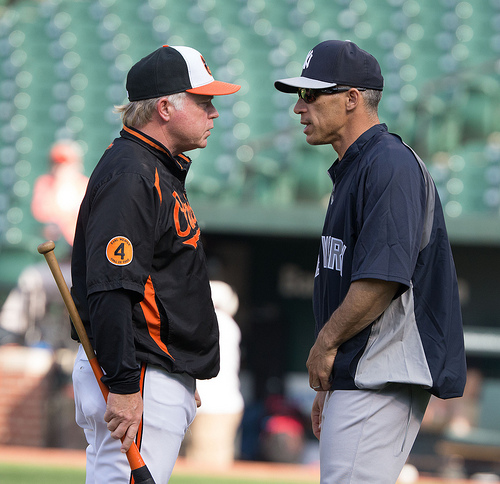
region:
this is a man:
[267, 18, 454, 481]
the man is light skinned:
[316, 104, 351, 126]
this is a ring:
[308, 379, 323, 392]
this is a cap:
[306, 43, 368, 76]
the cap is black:
[331, 41, 370, 84]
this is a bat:
[30, 237, 75, 324]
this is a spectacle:
[290, 90, 323, 103]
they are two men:
[61, 34, 363, 479]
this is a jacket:
[115, 186, 174, 294]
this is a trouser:
[343, 405, 390, 445]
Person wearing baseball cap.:
[283, 52, 386, 97]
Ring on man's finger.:
[309, 378, 326, 395]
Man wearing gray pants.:
[328, 414, 370, 452]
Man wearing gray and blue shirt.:
[296, 203, 446, 323]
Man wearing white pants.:
[84, 395, 181, 477]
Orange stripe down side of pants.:
[122, 378, 159, 481]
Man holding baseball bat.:
[61, 368, 160, 433]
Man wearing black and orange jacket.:
[96, 207, 192, 268]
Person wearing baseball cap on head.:
[114, 35, 224, 118]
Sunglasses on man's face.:
[291, 75, 353, 127]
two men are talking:
[93, 2, 460, 477]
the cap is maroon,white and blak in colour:
[106, 30, 243, 123]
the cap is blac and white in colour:
[262, 33, 389, 93]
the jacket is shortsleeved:
[301, 130, 487, 381]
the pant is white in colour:
[324, 398, 402, 483]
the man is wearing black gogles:
[260, 73, 360, 100]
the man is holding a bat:
[27, 69, 290, 460]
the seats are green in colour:
[36, 46, 116, 110]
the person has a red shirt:
[37, 109, 88, 255]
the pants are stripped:
[68, 365, 182, 473]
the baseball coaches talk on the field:
[72, 18, 470, 480]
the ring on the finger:
[309, 380, 323, 389]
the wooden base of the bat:
[39, 234, 99, 361]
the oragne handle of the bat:
[82, 358, 152, 468]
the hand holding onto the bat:
[104, 388, 144, 453]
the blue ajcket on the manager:
[310, 123, 471, 406]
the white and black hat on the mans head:
[111, 34, 243, 102]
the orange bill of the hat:
[188, 77, 248, 107]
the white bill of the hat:
[267, 76, 342, 99]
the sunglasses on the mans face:
[287, 83, 378, 105]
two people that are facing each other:
[43, 30, 446, 474]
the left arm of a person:
[315, 277, 399, 339]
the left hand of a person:
[307, 345, 338, 389]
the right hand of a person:
[88, 373, 149, 433]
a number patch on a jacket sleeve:
[98, 227, 138, 276]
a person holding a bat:
[35, 237, 194, 482]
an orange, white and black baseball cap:
[117, 20, 237, 132]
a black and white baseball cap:
[270, 24, 397, 100]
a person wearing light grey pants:
[317, 383, 434, 482]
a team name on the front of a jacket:
[164, 173, 204, 248]